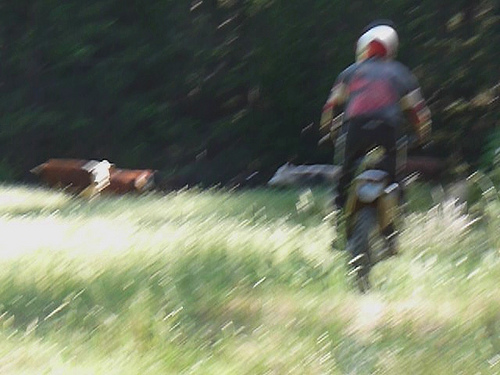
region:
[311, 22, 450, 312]
This is a person riding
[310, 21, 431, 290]
rider standing on moving motorcycle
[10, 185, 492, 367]
patches of tan and green grass shining and slanting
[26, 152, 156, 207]
rectangular brown object at end of grass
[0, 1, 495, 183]
trees forming a dark wall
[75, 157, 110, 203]
curved tan object reflecting light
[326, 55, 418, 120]
dark shirt with red design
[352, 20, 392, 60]
head within curve of silver helmet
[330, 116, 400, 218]
legs in dark jeans over bike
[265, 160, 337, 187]
slanted head on gray and black animal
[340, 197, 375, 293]
slanted black tire with silver prongs in back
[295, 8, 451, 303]
a person on a dirt bike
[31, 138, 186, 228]
two brown cows together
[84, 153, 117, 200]
white head on cow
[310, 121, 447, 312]
a bike in the air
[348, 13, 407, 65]
a helmet on the head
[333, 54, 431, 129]
a black and red shirt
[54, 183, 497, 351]
tall grass under bike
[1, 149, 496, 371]
a field of tall grass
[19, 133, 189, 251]
cows in the tall grass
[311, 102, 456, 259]
black pants on rider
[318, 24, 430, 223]
boy wearing jeans and riding bike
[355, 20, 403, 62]
boy in white helmet riding bike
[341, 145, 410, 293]
boy riding bike in middle of field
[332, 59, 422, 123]
boy riding dirt bike in gray shirt with red letters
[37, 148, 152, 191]
red truck on roadway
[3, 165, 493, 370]
grassy field with tall green grasses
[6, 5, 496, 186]
dark green trees in background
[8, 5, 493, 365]
sunny daytime outdoors afternoon scene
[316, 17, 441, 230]
boy standing on motorcycle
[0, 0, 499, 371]
the photo is very blurry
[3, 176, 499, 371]
the grass is long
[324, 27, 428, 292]
a person is on a bike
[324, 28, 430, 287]
the person is standing on the bike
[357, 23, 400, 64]
person wears a helmet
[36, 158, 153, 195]
a brown object on the left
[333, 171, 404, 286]
the person rides a dirt bike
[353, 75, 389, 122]
the shirt has a number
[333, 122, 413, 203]
the person wears black